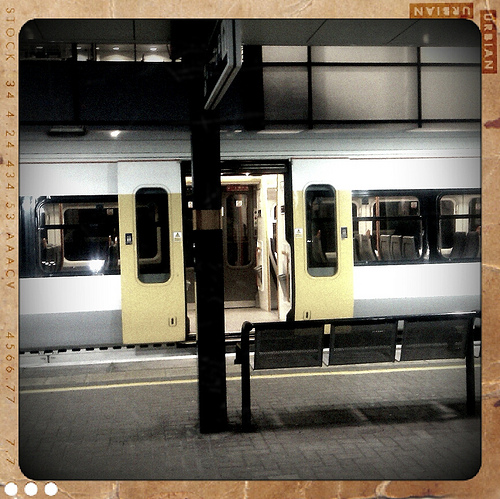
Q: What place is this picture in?
A: It is at the station.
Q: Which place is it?
A: It is a station.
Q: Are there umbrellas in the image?
A: No, there are no umbrellas.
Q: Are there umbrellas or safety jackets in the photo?
A: No, there are no umbrellas or safety jackets.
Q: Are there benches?
A: Yes, there is a bench.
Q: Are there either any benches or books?
A: Yes, there is a bench.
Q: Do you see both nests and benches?
A: No, there is a bench but no nests.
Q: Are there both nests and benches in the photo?
A: No, there is a bench but no nests.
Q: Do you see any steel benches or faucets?
A: Yes, there is a steel bench.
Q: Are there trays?
A: No, there are no trays.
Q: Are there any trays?
A: No, there are no trays.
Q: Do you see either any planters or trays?
A: No, there are no trays or planters.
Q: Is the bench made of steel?
A: Yes, the bench is made of steel.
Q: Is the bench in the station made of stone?
A: No, the bench is made of steel.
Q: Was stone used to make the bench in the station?
A: No, the bench is made of steel.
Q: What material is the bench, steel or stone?
A: The bench is made of steel.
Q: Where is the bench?
A: The bench is in the station.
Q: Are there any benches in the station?
A: Yes, there is a bench in the station.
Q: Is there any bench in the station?
A: Yes, there is a bench in the station.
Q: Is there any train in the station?
A: No, there is a bench in the station.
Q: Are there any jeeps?
A: No, there are no jeeps.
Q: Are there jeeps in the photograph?
A: No, there are no jeeps.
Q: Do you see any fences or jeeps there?
A: No, there are no jeeps or fences.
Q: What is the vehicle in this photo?
A: The vehicle is a car.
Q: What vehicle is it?
A: The vehicle is a car.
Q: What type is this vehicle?
A: This is a car.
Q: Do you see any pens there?
A: No, there are no pens.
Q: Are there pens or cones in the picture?
A: No, there are no pens or cones.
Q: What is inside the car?
A: The seat is inside the car.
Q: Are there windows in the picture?
A: Yes, there is a window.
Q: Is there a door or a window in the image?
A: Yes, there is a window.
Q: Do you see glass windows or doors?
A: Yes, there is a glass window.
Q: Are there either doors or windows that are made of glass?
A: Yes, the window is made of glass.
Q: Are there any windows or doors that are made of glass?
A: Yes, the window is made of glass.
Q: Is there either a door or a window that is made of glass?
A: Yes, the window is made of glass.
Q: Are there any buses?
A: No, there are no buses.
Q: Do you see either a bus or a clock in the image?
A: No, there are no buses or clocks.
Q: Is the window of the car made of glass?
A: Yes, the window is made of glass.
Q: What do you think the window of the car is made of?
A: The window is made of glass.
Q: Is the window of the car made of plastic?
A: No, the window is made of glass.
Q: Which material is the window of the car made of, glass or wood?
A: The window is made of glass.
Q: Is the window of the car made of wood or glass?
A: The window is made of glass.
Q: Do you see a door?
A: Yes, there is a door.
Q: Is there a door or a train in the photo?
A: Yes, there is a door.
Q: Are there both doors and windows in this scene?
A: Yes, there are both a door and a window.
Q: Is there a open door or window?
A: Yes, there is an open door.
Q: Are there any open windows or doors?
A: Yes, there is an open door.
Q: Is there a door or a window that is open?
A: Yes, the door is open.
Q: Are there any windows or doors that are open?
A: Yes, the door is open.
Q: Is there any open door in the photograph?
A: Yes, there is an open door.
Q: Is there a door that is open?
A: Yes, there is a door that is open.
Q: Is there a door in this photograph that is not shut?
A: Yes, there is a open door.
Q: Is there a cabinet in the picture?
A: No, there are no cabinets.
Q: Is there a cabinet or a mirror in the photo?
A: No, there are no cabinets or mirrors.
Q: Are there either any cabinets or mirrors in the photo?
A: No, there are no cabinets or mirrors.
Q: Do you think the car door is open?
A: Yes, the door is open.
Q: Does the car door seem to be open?
A: Yes, the door is open.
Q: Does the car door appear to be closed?
A: No, the door is open.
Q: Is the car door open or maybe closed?
A: The door is open.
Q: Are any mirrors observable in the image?
A: No, there are no mirrors.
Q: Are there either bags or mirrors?
A: No, there are no mirrors or bags.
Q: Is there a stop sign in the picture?
A: Yes, there is a stop sign.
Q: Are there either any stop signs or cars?
A: Yes, there is a stop sign.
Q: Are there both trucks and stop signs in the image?
A: No, there is a stop sign but no trucks.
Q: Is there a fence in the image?
A: No, there are no fences.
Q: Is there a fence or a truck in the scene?
A: No, there are no fences or trucks.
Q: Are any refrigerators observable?
A: No, there are no refrigerators.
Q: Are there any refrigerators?
A: No, there are no refrigerators.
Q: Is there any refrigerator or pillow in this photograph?
A: No, there are no refrigerators or pillows.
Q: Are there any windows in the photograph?
A: Yes, there is a window.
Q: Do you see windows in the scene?
A: Yes, there is a window.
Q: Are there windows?
A: Yes, there is a window.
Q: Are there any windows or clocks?
A: Yes, there is a window.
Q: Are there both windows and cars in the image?
A: Yes, there are both a window and a car.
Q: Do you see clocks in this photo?
A: No, there are no clocks.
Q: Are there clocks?
A: No, there are no clocks.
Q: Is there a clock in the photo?
A: No, there are no clocks.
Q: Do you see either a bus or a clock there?
A: No, there are no clocks or buses.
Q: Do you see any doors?
A: Yes, there is a door.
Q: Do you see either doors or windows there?
A: Yes, there is a door.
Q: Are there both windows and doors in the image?
A: Yes, there are both a door and windows.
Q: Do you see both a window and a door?
A: Yes, there are both a door and a window.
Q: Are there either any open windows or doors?
A: Yes, there is an open door.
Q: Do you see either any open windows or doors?
A: Yes, there is an open door.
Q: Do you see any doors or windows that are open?
A: Yes, the door is open.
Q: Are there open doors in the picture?
A: Yes, there is an open door.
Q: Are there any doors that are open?
A: Yes, there is a door that is open.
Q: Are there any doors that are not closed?
A: Yes, there is a open door.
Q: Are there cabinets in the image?
A: No, there are no cabinets.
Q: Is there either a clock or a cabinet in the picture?
A: No, there are no cabinets or clocks.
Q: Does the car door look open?
A: Yes, the door is open.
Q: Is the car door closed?
A: No, the door is open.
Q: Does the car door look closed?
A: No, the door is open.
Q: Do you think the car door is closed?
A: No, the door is open.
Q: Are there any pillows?
A: No, there are no pillows.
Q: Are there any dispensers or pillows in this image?
A: No, there are no pillows or dispensers.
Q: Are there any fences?
A: No, there are no fences.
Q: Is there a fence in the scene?
A: No, there are no fences.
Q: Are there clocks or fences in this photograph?
A: No, there are no fences or clocks.